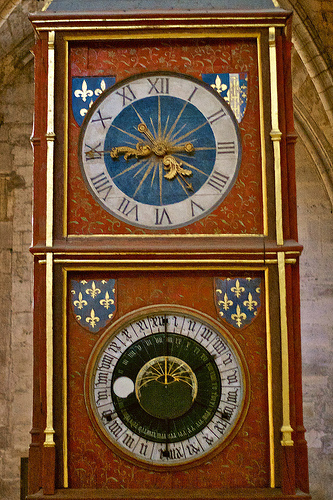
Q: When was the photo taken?
A: Day time.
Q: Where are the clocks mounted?
A: On a wall.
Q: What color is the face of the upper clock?
A: Blue.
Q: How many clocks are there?
A: 2.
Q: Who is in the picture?
A: No one.